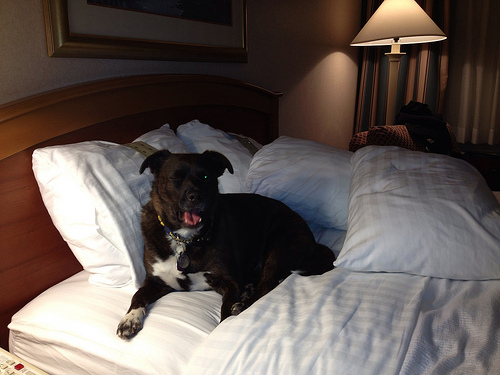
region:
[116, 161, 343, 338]
Dog sitting on the bed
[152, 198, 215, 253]
Collar around dog's neck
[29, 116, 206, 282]
Pillow on the side of the dog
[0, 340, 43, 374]
Phone next to bed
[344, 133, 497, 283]
Pillow on the bed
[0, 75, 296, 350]
Headboard against the wall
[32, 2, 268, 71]
Picture hanging over the bed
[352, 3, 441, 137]
Lamp in the background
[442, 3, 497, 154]
Curtain over the window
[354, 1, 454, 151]
Drape on the side of the window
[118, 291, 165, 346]
white paw on dog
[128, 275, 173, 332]
right leg on dog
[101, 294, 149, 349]
right paw on dog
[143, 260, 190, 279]
white fur on dog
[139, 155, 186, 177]
right ear on dog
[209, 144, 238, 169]
left ear on dog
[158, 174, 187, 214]
brown fur on dog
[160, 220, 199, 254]
brown collar on dog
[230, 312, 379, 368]
white sheets on bed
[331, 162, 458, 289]
white pillow on bed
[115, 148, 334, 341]
Black and white dog resting on bed.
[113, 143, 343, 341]
dog lying in bed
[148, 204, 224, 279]
collar on neck of dog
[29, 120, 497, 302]
white pillows on top of bed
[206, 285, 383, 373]
grey striped pattern on sheets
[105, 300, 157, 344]
spotted paw on sheets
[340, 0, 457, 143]
lamp next to bed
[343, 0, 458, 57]
white lamp shade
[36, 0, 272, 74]
framed painting over bed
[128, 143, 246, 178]
two floppy dog ears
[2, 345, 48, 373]
buttons on side of bed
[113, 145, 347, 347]
furry black and white dog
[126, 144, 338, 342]
dog lying on the bed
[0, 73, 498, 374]
bed with wooden headboard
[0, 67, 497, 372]
bed with white stripped sheets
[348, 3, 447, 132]
white lamp next to the bed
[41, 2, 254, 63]
picture above bed with gold frame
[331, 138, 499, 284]
white stripped pillow on the bed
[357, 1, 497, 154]
stripped green, tan, and red curtain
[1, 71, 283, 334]
wooden headboard of bed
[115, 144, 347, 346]
dog with one eye closed and mouth open